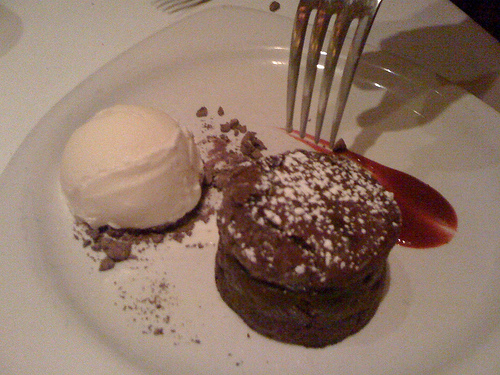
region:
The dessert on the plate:
[29, 63, 489, 349]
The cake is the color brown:
[213, 143, 404, 344]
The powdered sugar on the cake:
[242, 153, 387, 279]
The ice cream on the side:
[48, 100, 212, 251]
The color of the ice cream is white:
[64, 105, 196, 227]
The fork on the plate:
[281, 5, 395, 154]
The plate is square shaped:
[6, 6, 478, 311]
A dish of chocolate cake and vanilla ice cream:
[8, 65, 473, 367]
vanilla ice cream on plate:
[42, 112, 169, 233]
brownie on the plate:
[208, 157, 357, 302]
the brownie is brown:
[254, 294, 348, 324]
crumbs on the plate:
[77, 253, 227, 363]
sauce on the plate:
[377, 163, 472, 267]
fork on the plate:
[262, 5, 352, 150]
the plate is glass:
[190, 41, 269, 73]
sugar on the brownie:
[268, 176, 338, 265]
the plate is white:
[427, 302, 467, 361]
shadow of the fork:
[370, 34, 460, 133]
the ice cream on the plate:
[55, 93, 202, 238]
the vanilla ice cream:
[59, 96, 208, 237]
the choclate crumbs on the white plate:
[189, 94, 260, 164]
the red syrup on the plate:
[404, 164, 457, 253]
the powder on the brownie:
[221, 148, 398, 274]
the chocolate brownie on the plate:
[221, 149, 382, 337]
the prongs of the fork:
[268, 1, 382, 143]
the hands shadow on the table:
[354, 24, 492, 141]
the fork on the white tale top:
[143, 0, 203, 12]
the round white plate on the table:
[0, 34, 67, 363]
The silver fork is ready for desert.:
[284, 2, 362, 152]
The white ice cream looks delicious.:
[52, 99, 211, 239]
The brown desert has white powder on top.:
[200, 142, 408, 355]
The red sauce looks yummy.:
[270, 111, 465, 252]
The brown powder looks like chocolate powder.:
[60, 100, 282, 277]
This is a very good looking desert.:
[49, 90, 465, 352]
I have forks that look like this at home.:
[275, 47, 358, 153]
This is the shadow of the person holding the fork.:
[335, 5, 495, 164]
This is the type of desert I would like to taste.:
[202, 140, 408, 355]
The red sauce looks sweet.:
[275, 118, 470, 259]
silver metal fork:
[286, 3, 381, 156]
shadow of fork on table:
[153, 1, 227, 20]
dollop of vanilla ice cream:
[45, 98, 208, 229]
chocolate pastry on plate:
[217, 148, 405, 354]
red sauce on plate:
[297, 113, 462, 258]